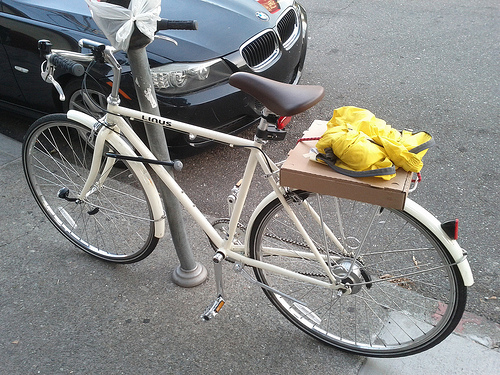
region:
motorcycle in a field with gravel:
[352, 328, 374, 355]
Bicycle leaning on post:
[23, 30, 468, 355]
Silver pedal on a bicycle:
[200, 299, 228, 324]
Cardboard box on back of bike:
[285, 115, 414, 204]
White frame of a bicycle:
[70, 101, 345, 293]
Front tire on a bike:
[22, 112, 161, 260]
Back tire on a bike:
[253, 185, 462, 359]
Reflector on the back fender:
[442, 216, 459, 241]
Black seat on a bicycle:
[235, 68, 325, 114]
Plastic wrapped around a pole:
[92, 1, 157, 45]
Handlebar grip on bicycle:
[43, 50, 83, 72]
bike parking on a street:
[3, 5, 494, 362]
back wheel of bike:
[232, 173, 484, 366]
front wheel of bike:
[11, 104, 170, 271]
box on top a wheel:
[237, 109, 480, 364]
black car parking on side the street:
[3, 6, 328, 209]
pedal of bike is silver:
[189, 251, 236, 332]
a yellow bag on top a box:
[270, 95, 439, 212]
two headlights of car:
[130, 0, 317, 100]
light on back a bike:
[437, 209, 469, 246]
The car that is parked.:
[6, 18, 350, 157]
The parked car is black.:
[8, 5, 361, 150]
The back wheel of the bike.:
[238, 167, 471, 356]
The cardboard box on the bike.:
[278, 108, 441, 220]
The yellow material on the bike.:
[312, 100, 425, 190]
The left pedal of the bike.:
[194, 250, 239, 332]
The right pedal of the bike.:
[223, 172, 260, 210]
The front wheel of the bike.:
[18, 110, 169, 272]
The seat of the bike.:
[232, 68, 329, 124]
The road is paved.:
[191, 150, 496, 305]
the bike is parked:
[20, 25, 447, 371]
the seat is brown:
[220, 52, 319, 133]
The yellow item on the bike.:
[320, 106, 431, 181]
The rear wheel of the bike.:
[249, 177, 494, 360]